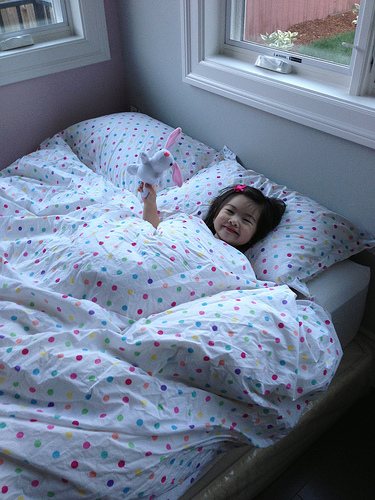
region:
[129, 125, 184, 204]
white and pink stuffed rabbit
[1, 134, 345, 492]
white cover with multicolored dots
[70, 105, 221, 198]
white pillow in left side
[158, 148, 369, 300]
white pillow with multicolored dots wher ekid is lying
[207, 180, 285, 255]
kid lying on bed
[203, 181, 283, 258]
large dark hair of little kid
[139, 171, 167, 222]
right hand holding stuffed rabbit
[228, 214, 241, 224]
big nose of little girl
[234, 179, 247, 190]
fuchsia loop on hair of girl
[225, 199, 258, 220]
dark eyebrows of little girl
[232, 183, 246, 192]
pink bow in the girl's hair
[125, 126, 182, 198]
white stuffed bunny with pink ears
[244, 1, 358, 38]
brown fencing seen through the window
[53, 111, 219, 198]
white pillow case with polka dots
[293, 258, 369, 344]
corner of white mattress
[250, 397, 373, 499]
small section of tiled floor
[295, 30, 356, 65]
grass seen through the window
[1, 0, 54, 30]
black deck rail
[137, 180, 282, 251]
little girl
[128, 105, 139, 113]
top of wall outlet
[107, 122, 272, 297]
a young girl lay in bed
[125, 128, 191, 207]
the girl has a stuffed bunny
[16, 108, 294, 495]
her bed spread is white with several polka dots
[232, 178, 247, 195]
the girl has a pink bow in her hair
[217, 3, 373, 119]
a window in the room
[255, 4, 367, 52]
a few plants can be seen outside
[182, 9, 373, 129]
the window frame is painted white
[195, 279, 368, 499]
the foundation is set on the floor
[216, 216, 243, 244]
the girl is smiling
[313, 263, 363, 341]
the sheet on the mattress is white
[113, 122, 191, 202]
stuffed animal bunny in the girl's hand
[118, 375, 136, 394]
red polka dot on the sheet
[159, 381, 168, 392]
purple dot on the sheet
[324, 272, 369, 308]
white mattress on the bed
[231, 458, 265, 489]
box spring under the mattress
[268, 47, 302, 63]
sticker on the window pane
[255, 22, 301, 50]
bush outside the window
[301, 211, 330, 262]
colorful dot pillow on the bed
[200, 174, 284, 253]
little girl laying down in the bed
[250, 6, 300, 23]
brown fence out the window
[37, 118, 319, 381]
a girl in her bed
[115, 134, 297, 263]
she is holding a toy bunny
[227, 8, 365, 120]
a window in her room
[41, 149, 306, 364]
a polka dot bed sheet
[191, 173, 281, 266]
the girl is smiling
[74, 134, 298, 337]
she looks comfortabel in her bed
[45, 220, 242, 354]
these polka dots are purple, pink, green and blue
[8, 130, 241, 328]
the sheets have a white base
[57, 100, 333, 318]
this child looks very happy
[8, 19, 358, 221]
the walls look gray